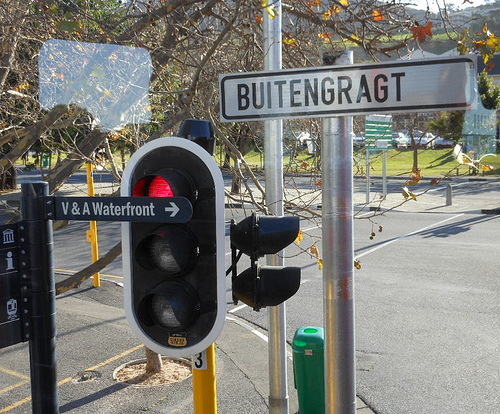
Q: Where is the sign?
A: On the post.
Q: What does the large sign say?
A: Buitengragt.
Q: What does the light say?
A: Stop.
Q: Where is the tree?
A: Behind the light.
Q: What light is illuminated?
A: Red.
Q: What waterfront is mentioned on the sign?
A: V&A.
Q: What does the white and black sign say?
A: Buitengragt.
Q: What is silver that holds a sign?
A: Post.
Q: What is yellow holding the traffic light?
A: Post.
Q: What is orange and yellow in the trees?
A: Leaves.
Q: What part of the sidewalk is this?
A: Corner.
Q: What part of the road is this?
A: Intersection.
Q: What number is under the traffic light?
A: 3.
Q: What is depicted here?
A: White sign with Buitengragt in black.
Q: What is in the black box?
A: A red light on.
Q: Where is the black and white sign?
A: On metal pole.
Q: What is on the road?
A: A white traffic line.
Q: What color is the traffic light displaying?
A: Red.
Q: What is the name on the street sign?
A: Buitengragt.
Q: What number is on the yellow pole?
A: 3.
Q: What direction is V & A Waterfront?
A: Right.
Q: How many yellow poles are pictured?
A: Two.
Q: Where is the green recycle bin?
A: Between the two metal poles.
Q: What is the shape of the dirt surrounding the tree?
A: A circle.